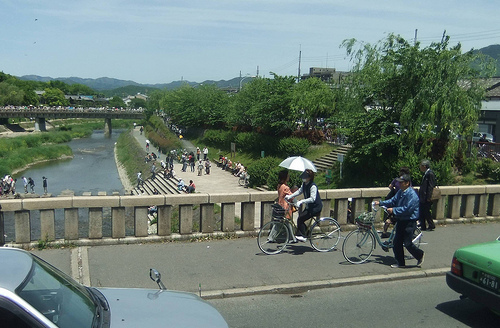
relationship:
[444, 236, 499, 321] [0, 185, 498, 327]
car on top of bridge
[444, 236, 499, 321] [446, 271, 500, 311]
car has bumper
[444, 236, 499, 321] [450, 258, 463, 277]
car has tail light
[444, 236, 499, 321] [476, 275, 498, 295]
car has license plate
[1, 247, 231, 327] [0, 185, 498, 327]
car on top of bridge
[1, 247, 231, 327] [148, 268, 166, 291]
car has side mirror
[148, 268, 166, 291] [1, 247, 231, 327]
side mirror attached to car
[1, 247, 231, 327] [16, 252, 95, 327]
car has windshield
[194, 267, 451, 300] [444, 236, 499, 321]
curb next to car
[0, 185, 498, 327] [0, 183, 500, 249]
bridge has safety railing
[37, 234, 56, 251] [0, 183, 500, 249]
weeds growing next to safety railing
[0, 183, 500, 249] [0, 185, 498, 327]
safety railing located on bridge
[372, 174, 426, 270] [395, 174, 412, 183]
man wearing cap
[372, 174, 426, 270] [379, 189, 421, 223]
man wearing jacket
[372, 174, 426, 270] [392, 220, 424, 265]
man wearing pants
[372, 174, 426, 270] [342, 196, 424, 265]
man pushing bike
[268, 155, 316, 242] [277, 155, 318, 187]
woman carrying umbrella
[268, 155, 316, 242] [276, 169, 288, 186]
woman has hair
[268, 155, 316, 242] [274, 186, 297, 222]
woman wearing tunic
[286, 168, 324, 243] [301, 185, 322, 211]
woman wearing vest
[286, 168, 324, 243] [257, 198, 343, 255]
woman riding bike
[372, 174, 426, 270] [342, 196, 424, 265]
man walking beside bike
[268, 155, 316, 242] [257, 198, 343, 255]
woman riding bike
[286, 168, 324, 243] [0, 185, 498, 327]
woman riding over bridge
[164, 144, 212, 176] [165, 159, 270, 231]
crowd standing on landing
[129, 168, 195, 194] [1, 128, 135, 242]
stairs leading to river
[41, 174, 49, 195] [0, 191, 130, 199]
person walking on stones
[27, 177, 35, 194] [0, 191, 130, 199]
person walking on stones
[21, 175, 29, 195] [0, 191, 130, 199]
person walking on stones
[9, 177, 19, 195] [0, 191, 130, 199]
person walking on stones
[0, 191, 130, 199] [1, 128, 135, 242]
stones across river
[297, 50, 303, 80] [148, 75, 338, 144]
power pole behind trees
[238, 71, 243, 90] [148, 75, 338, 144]
power pole behind trees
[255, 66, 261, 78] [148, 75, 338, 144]
power pole behind trees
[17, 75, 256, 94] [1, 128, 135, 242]
mountains behind river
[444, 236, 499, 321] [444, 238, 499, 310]
car has car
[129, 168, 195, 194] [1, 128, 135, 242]
stairs going down to river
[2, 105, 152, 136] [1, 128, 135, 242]
bridge over river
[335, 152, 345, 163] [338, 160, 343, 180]
sign attached to post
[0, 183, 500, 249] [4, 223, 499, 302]
safety railing next to sidewalk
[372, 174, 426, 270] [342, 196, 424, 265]
man walking bike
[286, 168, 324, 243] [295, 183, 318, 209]
woman wearing sleeve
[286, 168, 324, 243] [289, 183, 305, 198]
woman wearing sleeve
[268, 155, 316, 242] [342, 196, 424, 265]
woman riding bike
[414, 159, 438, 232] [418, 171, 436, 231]
man wearing suit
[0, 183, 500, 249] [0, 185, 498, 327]
safety railing on top of bridge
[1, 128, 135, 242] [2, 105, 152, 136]
river beneath bridge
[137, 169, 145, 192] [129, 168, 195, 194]
person on top of stairs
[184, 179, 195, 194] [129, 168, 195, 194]
person on top of stairs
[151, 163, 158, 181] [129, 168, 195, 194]
person on top of stairs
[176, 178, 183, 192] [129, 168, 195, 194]
person on top of stairs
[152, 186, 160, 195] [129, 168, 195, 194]
person on top of stairs